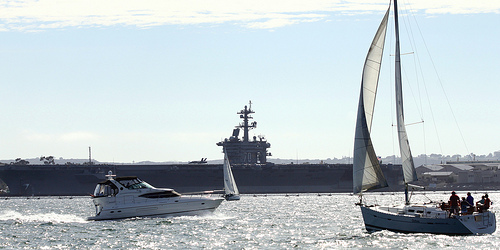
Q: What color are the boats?
A: White.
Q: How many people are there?
A: 7.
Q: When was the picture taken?
A: Daytime.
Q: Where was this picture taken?
A: On the ocean.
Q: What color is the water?
A: Blue.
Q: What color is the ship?
A: Gray.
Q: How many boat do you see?
A: 3.